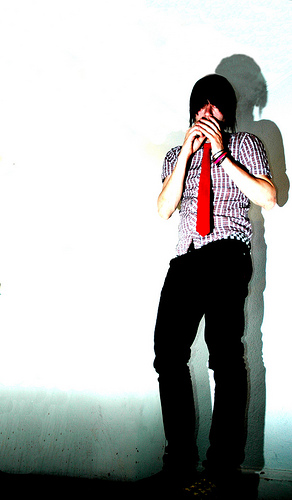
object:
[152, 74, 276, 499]
boy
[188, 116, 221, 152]
fingers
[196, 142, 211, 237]
tie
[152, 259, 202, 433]
legs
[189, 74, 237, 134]
hair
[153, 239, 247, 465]
pants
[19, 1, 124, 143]
wall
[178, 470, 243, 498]
shoes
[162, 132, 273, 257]
shirt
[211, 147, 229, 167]
bracelets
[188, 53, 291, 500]
shadow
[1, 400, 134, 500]
floor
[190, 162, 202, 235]
buttons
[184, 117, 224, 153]
hands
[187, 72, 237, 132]
head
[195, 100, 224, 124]
face